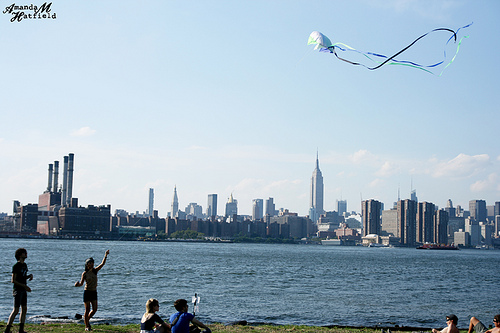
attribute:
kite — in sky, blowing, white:
[286, 22, 499, 96]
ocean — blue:
[57, 242, 498, 307]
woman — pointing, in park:
[78, 250, 111, 332]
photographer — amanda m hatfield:
[7, 7, 64, 30]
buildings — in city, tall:
[17, 119, 499, 246]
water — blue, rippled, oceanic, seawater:
[34, 248, 486, 303]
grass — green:
[214, 317, 395, 326]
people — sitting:
[134, 294, 498, 330]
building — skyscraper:
[286, 147, 327, 231]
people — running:
[3, 242, 136, 332]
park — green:
[19, 244, 472, 331]